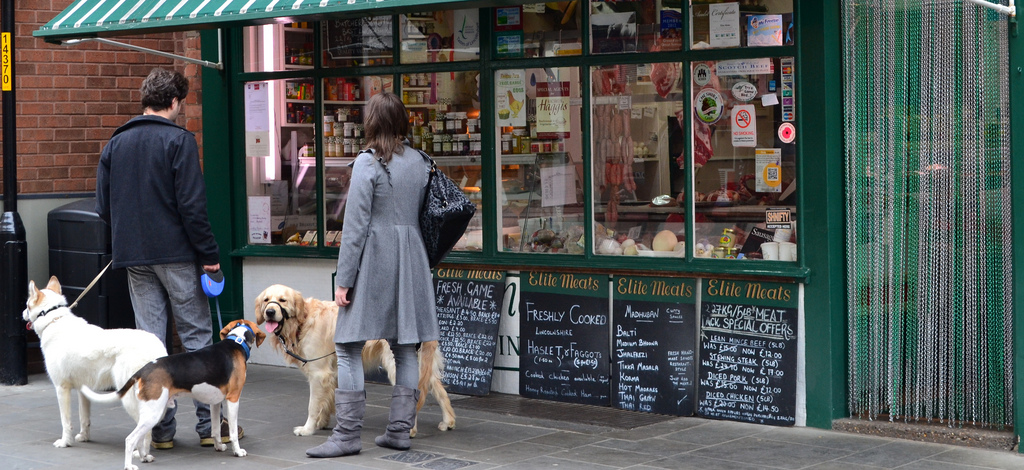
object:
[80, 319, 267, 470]
dog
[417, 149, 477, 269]
purse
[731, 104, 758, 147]
sign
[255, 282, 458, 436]
brown dog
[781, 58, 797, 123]
window sticker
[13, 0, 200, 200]
wall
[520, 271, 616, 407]
sign